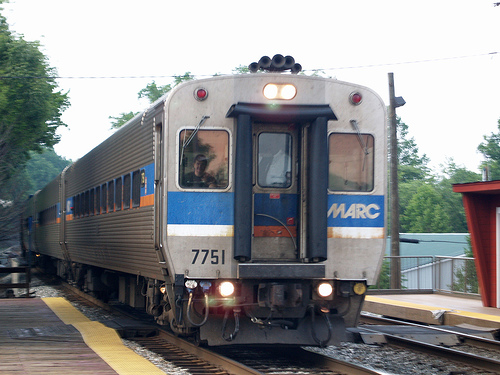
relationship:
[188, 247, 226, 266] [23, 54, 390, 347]
number displayed on a train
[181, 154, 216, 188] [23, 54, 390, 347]
man driving a train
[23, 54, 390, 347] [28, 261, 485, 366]
train on tracks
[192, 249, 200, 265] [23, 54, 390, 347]
number on train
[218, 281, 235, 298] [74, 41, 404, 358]
light on train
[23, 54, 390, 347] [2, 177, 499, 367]
train near station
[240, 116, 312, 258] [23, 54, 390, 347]
door on train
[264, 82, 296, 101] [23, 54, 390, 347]
light on train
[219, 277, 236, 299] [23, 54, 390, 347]
light on train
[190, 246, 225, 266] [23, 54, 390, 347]
numbers on train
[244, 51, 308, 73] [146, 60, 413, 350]
horn on train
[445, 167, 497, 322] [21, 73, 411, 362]
building near train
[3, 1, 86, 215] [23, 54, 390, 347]
tree near train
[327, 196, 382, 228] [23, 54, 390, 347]
name on train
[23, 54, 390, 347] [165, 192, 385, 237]
train with a stripe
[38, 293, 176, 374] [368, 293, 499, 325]
yellow line on yellow line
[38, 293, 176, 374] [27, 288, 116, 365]
yellow line on ground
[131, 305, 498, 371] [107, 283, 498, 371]
gravel on tracks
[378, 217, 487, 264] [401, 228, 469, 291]
roof of a building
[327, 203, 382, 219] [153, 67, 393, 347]
name on train